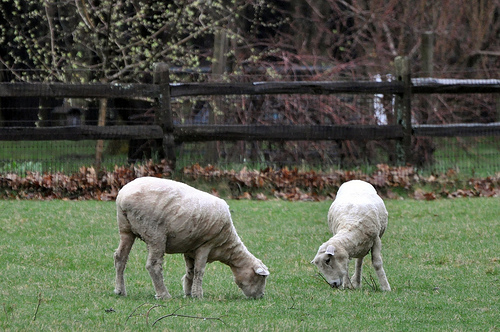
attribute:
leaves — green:
[7, 2, 257, 107]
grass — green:
[1, 137, 500, 330]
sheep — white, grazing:
[110, 173, 395, 305]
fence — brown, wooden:
[2, 60, 500, 184]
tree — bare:
[1, 0, 257, 162]